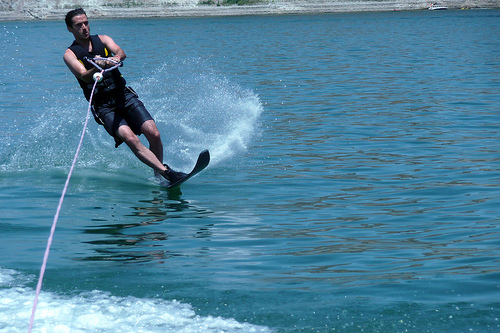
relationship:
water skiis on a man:
[164, 147, 214, 187] [64, 6, 189, 183]